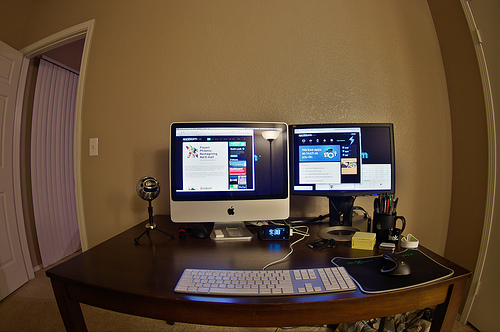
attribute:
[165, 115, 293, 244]
computer monitor — white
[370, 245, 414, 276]
mouse — black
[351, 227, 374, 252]
stack — yellow, post-it notes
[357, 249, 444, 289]
mouse — black, gray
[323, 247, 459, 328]
mouse pad — black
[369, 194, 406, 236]
mug — black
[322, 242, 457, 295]
mouse pad — black, green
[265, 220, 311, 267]
cord — long, white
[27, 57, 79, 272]
door — white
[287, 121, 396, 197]
monitor — black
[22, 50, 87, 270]
blinds — white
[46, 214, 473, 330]
desk — brown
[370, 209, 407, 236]
mug — black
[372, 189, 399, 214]
pens — various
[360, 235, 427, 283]
computer mouse — dark gray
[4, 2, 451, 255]
wall — tan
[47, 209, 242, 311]
wooden desk — dark brown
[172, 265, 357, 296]
keyboard — white, slim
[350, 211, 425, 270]
cup — black, coffee cup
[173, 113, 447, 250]
monitor — apple monitor, on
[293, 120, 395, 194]
monitor — black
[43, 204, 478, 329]
desk — black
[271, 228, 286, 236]
usb — black , red 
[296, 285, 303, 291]
key — white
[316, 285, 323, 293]
key — white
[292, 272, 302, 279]
key — white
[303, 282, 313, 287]
key — white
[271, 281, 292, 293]
key — white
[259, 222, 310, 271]
cable — white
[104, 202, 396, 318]
concrete — Grey 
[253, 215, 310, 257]
charger — blue 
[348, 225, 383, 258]
sticky notes — yellow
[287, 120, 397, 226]
monitor — black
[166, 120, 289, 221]
screen — grey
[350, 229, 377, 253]
notes — yellow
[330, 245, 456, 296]
trim — white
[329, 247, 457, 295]
border — white